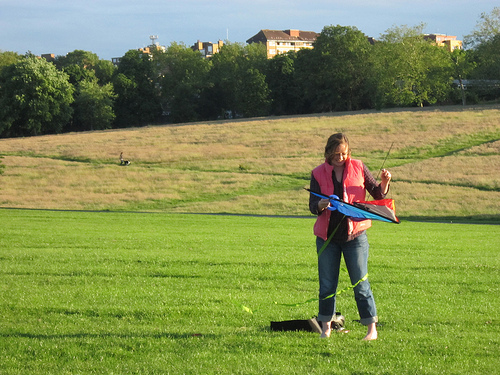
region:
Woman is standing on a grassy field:
[3, 104, 498, 373]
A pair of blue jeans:
[311, 233, 381, 328]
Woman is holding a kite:
[301, 129, 403, 262]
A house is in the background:
[241, 26, 326, 63]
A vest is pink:
[309, 158, 374, 243]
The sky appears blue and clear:
[1, 2, 499, 62]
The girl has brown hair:
[317, 128, 357, 171]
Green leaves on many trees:
[2, 6, 498, 139]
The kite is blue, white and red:
[300, 181, 403, 227]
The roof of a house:
[243, 27, 321, 43]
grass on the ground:
[78, 268, 195, 320]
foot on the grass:
[356, 321, 384, 340]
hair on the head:
[322, 134, 342, 144]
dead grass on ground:
[110, 182, 180, 198]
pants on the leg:
[352, 248, 362, 261]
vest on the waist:
[345, 173, 360, 195]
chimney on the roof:
[286, 28, 298, 38]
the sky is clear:
[110, 20, 186, 30]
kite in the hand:
[334, 202, 395, 226]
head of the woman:
[333, 146, 350, 166]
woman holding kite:
[301, 129, 413, 358]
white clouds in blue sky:
[55, 10, 118, 42]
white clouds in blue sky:
[98, 11, 131, 33]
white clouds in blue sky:
[22, 3, 63, 27]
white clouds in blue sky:
[415, 2, 461, 21]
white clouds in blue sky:
[354, 3, 385, 19]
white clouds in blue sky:
[187, 8, 224, 36]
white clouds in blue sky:
[285, 4, 317, 28]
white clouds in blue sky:
[139, 4, 202, 49]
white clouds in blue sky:
[74, 11, 124, 31]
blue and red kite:
[301, 173, 403, 232]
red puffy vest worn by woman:
[303, 164, 373, 244]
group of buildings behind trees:
[136, 20, 466, 63]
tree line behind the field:
[12, 47, 477, 108]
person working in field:
[110, 147, 139, 173]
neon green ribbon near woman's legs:
[272, 260, 382, 307]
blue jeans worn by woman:
[308, 231, 380, 328]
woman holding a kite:
[288, 115, 463, 363]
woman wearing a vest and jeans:
[303, 127, 385, 342]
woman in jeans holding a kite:
[295, 127, 397, 348]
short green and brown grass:
[5, 223, 55, 267]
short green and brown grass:
[174, 269, 231, 300]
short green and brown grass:
[405, 216, 440, 241]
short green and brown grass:
[441, 272, 465, 293]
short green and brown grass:
[400, 313, 464, 361]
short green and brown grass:
[147, 241, 212, 286]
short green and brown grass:
[72, 248, 140, 295]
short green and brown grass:
[174, 249, 228, 276]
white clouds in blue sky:
[81, 13, 132, 44]